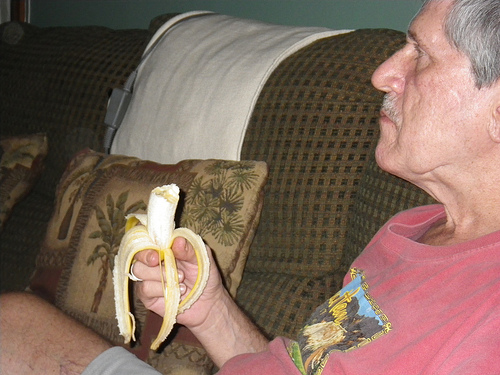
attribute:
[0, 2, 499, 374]
man — elderly, sitting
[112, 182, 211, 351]
banana — peeled, half eaten, marked, eaten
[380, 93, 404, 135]
facial hair — grey, white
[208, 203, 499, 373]
shirt — pink, red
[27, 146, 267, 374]
pillow — flowered, tropical, cornered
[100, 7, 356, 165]
blanket — white, electric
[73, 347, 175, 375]
shorts — khaki, grey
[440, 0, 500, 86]
hair — salt, pepper, grey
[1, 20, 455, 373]
couch — checkered, brown